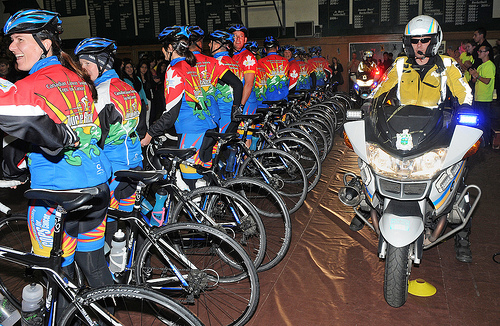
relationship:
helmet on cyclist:
[159, 24, 194, 42] [147, 24, 227, 174]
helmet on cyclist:
[0, 8, 61, 35] [4, 2, 104, 317]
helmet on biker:
[399, 17, 444, 58] [349, 8, 473, 263]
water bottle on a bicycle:
[107, 227, 127, 274] [0, 171, 259, 325]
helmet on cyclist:
[74, 34, 121, 56] [72, 32, 158, 284]